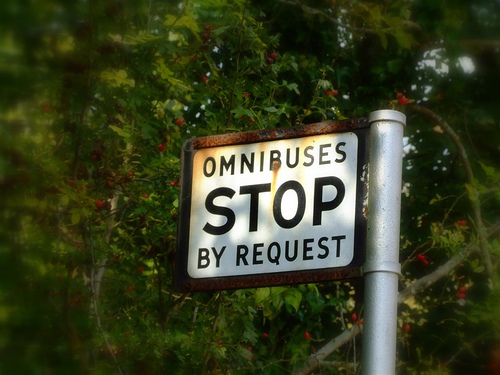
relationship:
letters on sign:
[198, 145, 356, 259] [169, 113, 370, 296]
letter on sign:
[195, 246, 211, 267] [184, 132, 361, 277]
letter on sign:
[208, 243, 227, 267] [184, 132, 361, 277]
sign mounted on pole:
[169, 113, 370, 296] [359, 106, 406, 358]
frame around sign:
[177, 119, 367, 294] [169, 113, 370, 296]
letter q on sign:
[264, 240, 285, 268] [169, 113, 370, 296]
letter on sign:
[216, 152, 238, 177] [166, 112, 366, 276]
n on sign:
[240, 149, 253, 174] [169, 113, 370, 296]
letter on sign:
[269, 149, 281, 172] [169, 113, 370, 296]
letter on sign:
[257, 145, 267, 174] [184, 132, 361, 277]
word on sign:
[195, 137, 347, 269] [169, 113, 370, 296]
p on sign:
[309, 175, 347, 227] [158, 103, 414, 373]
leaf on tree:
[0, 0, 499, 375] [91, 18, 313, 103]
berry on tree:
[415, 253, 429, 265] [191, 0, 483, 122]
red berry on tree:
[458, 283, 471, 299] [191, 0, 483, 122]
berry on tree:
[175, 117, 185, 126] [8, 1, 187, 373]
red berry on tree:
[95, 198, 106, 208] [8, 1, 187, 373]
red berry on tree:
[156, 142, 165, 152] [8, 1, 187, 373]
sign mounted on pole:
[169, 113, 370, 296] [358, 99, 406, 374]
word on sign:
[195, 137, 347, 269] [184, 132, 361, 277]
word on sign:
[235, 233, 345, 266] [184, 132, 361, 277]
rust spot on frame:
[181, 263, 357, 293] [177, 119, 367, 294]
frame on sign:
[177, 119, 367, 294] [169, 113, 370, 296]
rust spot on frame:
[173, 266, 366, 293] [177, 119, 367, 294]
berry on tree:
[301, 331, 311, 343] [5, 10, 492, 371]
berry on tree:
[200, 22, 210, 34] [5, 10, 492, 371]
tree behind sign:
[5, 10, 492, 371] [169, 113, 370, 296]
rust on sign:
[175, 126, 352, 146] [175, 113, 362, 290]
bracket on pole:
[363, 257, 403, 277] [365, 107, 408, 372]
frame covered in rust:
[177, 119, 367, 294] [176, 116, 362, 291]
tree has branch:
[5, 10, 492, 371] [305, 220, 497, 366]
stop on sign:
[205, 175, 348, 237] [169, 113, 370, 296]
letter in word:
[218, 154, 235, 176] [201, 138, 346, 174]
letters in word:
[318, 141, 348, 164] [195, 137, 347, 269]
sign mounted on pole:
[169, 113, 370, 296] [155, 101, 390, 307]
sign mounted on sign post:
[169, 113, 370, 296] [177, 105, 408, 373]